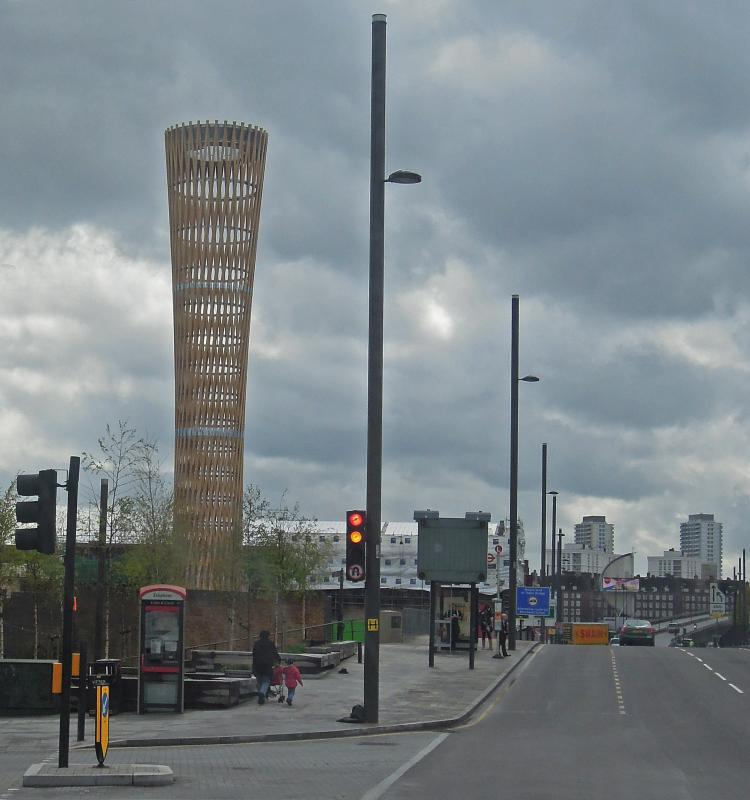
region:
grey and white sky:
[501, 54, 659, 296]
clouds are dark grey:
[437, 12, 651, 376]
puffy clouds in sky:
[495, 80, 681, 384]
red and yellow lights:
[327, 496, 365, 549]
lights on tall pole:
[325, 9, 430, 561]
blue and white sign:
[501, 571, 550, 626]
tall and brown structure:
[141, 110, 267, 626]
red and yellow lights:
[327, 495, 375, 579]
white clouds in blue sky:
[608, 192, 691, 258]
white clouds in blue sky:
[297, 391, 346, 440]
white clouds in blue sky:
[68, 106, 128, 196]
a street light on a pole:
[368, 157, 425, 714]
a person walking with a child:
[249, 629, 303, 715]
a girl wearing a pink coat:
[277, 659, 308, 692]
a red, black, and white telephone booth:
[136, 581, 187, 723]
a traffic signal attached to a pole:
[341, 508, 384, 571]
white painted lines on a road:
[605, 652, 629, 720]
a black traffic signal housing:
[12, 466, 59, 557]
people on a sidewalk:
[247, 630, 317, 722]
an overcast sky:
[1, 1, 741, 565]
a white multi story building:
[680, 512, 725, 579]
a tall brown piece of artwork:
[155, 107, 267, 584]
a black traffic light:
[12, 460, 59, 557]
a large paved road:
[401, 626, 746, 795]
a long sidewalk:
[137, 614, 542, 734]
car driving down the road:
[615, 616, 656, 643]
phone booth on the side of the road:
[138, 581, 188, 712]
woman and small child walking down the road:
[251, 628, 303, 704]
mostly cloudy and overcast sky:
[12, 12, 747, 585]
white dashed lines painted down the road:
[669, 641, 739, 692]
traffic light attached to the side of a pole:
[342, 507, 378, 582]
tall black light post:
[503, 288, 539, 649]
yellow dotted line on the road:
[607, 645, 628, 716]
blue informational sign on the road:
[515, 582, 553, 620]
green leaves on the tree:
[265, 539, 302, 582]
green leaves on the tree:
[116, 549, 156, 573]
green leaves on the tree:
[166, 545, 175, 583]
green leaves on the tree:
[119, 485, 162, 546]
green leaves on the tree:
[300, 555, 330, 605]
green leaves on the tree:
[286, 518, 320, 572]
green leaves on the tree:
[33, 559, 55, 604]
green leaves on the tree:
[262, 499, 304, 541]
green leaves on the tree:
[250, 532, 310, 603]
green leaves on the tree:
[117, 500, 166, 591]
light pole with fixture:
[354, 5, 395, 749]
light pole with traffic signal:
[339, 5, 421, 742]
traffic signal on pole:
[325, 479, 407, 736]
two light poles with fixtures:
[358, 11, 536, 721]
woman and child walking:
[245, 617, 311, 715]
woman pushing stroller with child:
[245, 625, 310, 726]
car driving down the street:
[609, 607, 664, 654]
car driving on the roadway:
[617, 612, 666, 654]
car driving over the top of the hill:
[612, 607, 660, 656]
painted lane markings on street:
[608, 656, 629, 722]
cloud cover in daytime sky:
[2, 2, 747, 572]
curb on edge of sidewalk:
[130, 635, 538, 744]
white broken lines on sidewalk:
[677, 644, 748, 695]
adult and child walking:
[252, 630, 306, 706]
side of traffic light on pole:
[15, 452, 81, 768]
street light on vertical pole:
[503, 292, 540, 645]